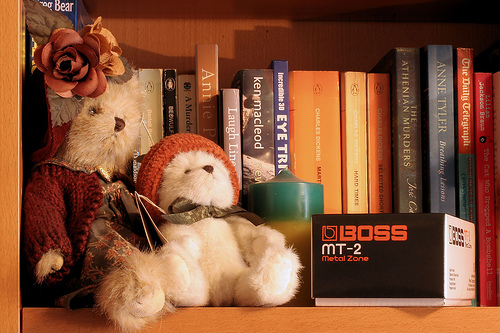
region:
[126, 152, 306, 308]
A white beautiful teddy bear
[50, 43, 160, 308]
A white beautiful teddy bear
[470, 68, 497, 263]
a book arrenged on the shelf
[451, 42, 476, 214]
a book arrenged on the shelf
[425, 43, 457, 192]
a book arrenged on the shelf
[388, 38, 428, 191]
a book arrenged on the shelf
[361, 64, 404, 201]
a book arrenged on the shelf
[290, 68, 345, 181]
a book arrenged on the shelf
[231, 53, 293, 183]
a book arrenged on the shelf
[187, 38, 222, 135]
a book arrenged on the shelf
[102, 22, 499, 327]
books in the shelf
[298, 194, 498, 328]
a box in the shelf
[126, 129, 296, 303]
A teddy bear wearing a hat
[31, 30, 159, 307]
A teddy bear wearing a sweater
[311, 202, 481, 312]
A box on the shelf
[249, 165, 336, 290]
A candle on the shelf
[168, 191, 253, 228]
The bow on the teddy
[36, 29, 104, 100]
A pink rose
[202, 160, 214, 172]
The nose of the teddy bear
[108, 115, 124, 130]
The nose of the teddy bear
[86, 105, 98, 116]
An eye of the teddy bear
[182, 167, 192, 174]
An eye of the bear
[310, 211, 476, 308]
a box for a boss guitar pedal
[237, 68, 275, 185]
a book is on a shelf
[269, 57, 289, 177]
a book is on a shelf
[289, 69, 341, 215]
a book is on a shelf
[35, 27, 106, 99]
a rose on a hat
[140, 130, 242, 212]
a hat on a bear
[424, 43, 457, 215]
a light blue book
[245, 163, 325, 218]
green section of a candle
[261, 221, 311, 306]
yellow section of a candle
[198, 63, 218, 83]
The letter is white.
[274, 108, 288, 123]
The letter is white.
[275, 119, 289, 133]
The letter is white.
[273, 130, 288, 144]
The letter is white.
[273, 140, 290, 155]
The letter is white.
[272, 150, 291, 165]
The letter is white.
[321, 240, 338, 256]
The letter is white.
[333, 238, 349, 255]
The letter is white.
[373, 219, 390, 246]
The letter is orange.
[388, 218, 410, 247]
The letter is orange.